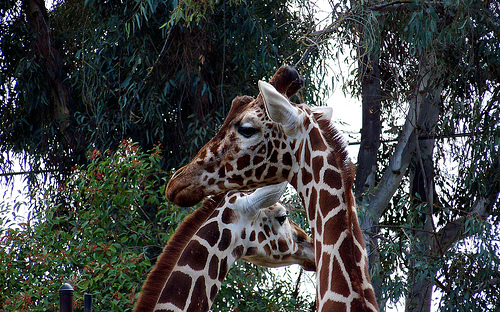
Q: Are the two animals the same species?
A: Yes, all the animals are giraffes.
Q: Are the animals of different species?
A: No, all the animals are giraffes.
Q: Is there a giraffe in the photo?
A: Yes, there is a giraffe.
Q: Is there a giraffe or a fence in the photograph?
A: Yes, there is a giraffe.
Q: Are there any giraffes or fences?
A: Yes, there is a giraffe.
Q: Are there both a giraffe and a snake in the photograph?
A: No, there is a giraffe but no snakes.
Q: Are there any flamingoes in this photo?
A: No, there are no flamingoes.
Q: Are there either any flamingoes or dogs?
A: No, there are no flamingoes or dogs.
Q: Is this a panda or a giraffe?
A: This is a giraffe.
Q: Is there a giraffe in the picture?
A: Yes, there is a giraffe.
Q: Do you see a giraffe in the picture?
A: Yes, there is a giraffe.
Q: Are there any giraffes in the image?
A: Yes, there is a giraffe.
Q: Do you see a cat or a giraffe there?
A: Yes, there is a giraffe.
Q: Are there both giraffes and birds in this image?
A: No, there is a giraffe but no birds.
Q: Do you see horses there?
A: No, there are no horses.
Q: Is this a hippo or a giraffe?
A: This is a giraffe.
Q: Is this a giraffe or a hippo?
A: This is a giraffe.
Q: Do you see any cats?
A: No, there are no cats.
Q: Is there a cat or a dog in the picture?
A: No, there are no cats or dogs.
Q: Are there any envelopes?
A: No, there are no envelopes.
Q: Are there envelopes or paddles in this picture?
A: No, there are no envelopes or paddles.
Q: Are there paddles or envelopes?
A: No, there are no envelopes or paddles.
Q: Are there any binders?
A: No, there are no binders.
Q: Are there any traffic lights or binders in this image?
A: No, there are no binders or traffic lights.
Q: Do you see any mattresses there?
A: No, there are no mattresses.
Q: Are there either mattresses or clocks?
A: No, there are no mattresses or clocks.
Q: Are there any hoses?
A: No, there are no hoses.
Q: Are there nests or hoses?
A: No, there are no hoses or nests.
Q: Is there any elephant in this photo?
A: No, there are no elephants.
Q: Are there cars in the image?
A: No, there are no cars.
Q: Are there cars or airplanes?
A: No, there are no cars or airplanes.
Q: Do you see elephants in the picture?
A: No, there are no elephants.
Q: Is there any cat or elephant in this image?
A: No, there are no elephants or cats.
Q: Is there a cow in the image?
A: No, there are no cows.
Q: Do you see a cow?
A: No, there are no cows.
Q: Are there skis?
A: No, there are no skis.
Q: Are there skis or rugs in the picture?
A: No, there are no skis or rugs.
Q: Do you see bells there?
A: No, there are no bells.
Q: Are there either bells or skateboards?
A: No, there are no bells or skateboards.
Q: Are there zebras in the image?
A: No, there are no zebras.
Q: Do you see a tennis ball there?
A: No, there are no tennis balls.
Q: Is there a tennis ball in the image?
A: No, there are no tennis balls.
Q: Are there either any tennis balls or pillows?
A: No, there are no tennis balls or pillows.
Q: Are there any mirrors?
A: No, there are no mirrors.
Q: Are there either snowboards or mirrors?
A: No, there are no mirrors or snowboards.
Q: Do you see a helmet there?
A: No, there are no helmets.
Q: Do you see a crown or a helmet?
A: No, there are no helmets or crowns.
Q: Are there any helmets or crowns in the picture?
A: No, there are no helmets or crowns.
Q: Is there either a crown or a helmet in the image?
A: No, there are no helmets or crowns.